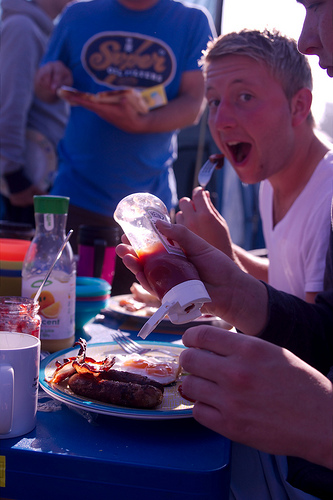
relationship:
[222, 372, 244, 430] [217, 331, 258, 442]
spots on knuckles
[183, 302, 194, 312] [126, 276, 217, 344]
ketchup on lid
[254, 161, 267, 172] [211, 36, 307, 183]
spot on face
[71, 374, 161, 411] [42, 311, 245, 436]
sausage on plate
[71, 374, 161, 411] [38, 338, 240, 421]
sausage on plate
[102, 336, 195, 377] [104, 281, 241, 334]
eggs on plate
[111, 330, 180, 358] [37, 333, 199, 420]
fork on plate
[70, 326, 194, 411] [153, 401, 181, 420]
meal on plate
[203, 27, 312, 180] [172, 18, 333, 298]
head on man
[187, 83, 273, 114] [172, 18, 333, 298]
eyes are on man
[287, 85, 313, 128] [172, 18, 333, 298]
ear on man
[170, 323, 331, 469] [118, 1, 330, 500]
hand on person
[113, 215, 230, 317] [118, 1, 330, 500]
hand on person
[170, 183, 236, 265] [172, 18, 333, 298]
hand on man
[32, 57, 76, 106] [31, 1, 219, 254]
hand on man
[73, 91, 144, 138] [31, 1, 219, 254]
hand on man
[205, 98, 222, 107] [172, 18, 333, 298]
eye on man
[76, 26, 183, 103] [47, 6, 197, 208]
logo on shirt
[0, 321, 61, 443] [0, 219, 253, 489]
coffee mug on table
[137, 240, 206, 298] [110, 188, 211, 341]
red ketchup in plastic bottle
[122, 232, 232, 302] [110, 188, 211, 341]
hand holding plastic bottle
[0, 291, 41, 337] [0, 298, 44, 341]
jar has red jelly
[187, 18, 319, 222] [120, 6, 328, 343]
man wearing shirt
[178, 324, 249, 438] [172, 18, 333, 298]
fingers of a man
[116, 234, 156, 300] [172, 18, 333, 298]
fingers of a man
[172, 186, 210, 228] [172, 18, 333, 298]
fingers of a man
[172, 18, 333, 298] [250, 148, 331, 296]
man wearing a shirt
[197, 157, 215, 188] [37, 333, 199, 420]
fork on a plate